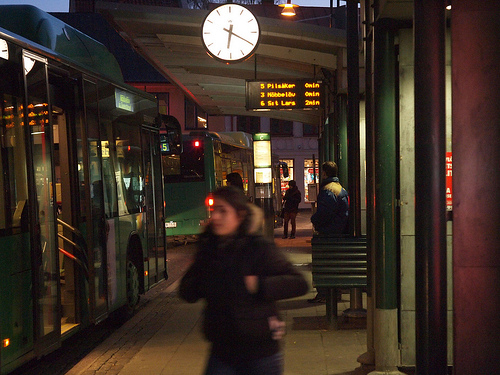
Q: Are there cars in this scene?
A: No, there are no cars.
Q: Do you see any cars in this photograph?
A: No, there are no cars.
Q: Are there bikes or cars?
A: No, there are no cars or bikes.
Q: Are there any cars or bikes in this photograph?
A: No, there are no cars or bikes.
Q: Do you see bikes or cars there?
A: No, there are no cars or bikes.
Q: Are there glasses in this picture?
A: No, there are no glasses.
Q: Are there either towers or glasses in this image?
A: No, there are no glasses or towers.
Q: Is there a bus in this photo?
A: Yes, there is a bus.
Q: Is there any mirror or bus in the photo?
A: Yes, there is a bus.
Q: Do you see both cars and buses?
A: No, there is a bus but no cars.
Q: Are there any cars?
A: No, there are no cars.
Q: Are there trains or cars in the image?
A: No, there are no cars or trains.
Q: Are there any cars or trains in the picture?
A: No, there are no cars or trains.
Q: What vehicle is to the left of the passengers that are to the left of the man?
A: The vehicle is a bus.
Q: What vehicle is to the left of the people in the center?
A: The vehicle is a bus.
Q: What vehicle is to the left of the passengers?
A: The vehicle is a bus.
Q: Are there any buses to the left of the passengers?
A: Yes, there is a bus to the left of the passengers.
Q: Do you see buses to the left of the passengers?
A: Yes, there is a bus to the left of the passengers.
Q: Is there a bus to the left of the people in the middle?
A: Yes, there is a bus to the left of the passengers.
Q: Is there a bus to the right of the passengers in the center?
A: No, the bus is to the left of the passengers.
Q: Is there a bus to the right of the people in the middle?
A: No, the bus is to the left of the passengers.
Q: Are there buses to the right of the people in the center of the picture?
A: No, the bus is to the left of the passengers.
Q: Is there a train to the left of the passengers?
A: No, there is a bus to the left of the passengers.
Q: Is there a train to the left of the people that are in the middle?
A: No, there is a bus to the left of the passengers.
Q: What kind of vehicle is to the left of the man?
A: The vehicle is a bus.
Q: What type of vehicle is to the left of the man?
A: The vehicle is a bus.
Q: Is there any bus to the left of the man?
A: Yes, there is a bus to the left of the man.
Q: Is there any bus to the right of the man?
A: No, the bus is to the left of the man.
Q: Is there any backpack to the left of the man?
A: No, there is a bus to the left of the man.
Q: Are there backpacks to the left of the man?
A: No, there is a bus to the left of the man.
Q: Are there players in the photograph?
A: No, there are no players.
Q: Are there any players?
A: No, there are no players.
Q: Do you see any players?
A: No, there are no players.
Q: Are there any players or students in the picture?
A: No, there are no players or students.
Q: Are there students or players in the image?
A: No, there are no players or students.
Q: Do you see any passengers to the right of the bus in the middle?
A: Yes, there are passengers to the right of the bus.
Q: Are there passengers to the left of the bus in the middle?
A: No, the passengers are to the right of the bus.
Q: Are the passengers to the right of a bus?
A: Yes, the passengers are to the right of a bus.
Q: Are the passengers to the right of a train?
A: No, the passengers are to the right of a bus.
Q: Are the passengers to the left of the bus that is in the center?
A: No, the passengers are to the right of the bus.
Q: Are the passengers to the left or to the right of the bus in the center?
A: The passengers are to the right of the bus.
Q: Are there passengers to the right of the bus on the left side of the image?
A: Yes, there are passengers to the right of the bus.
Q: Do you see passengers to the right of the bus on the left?
A: Yes, there are passengers to the right of the bus.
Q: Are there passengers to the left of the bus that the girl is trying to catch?
A: No, the passengers are to the right of the bus.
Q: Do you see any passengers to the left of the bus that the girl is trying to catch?
A: No, the passengers are to the right of the bus.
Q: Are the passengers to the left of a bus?
A: No, the passengers are to the right of a bus.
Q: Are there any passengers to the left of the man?
A: Yes, there are passengers to the left of the man.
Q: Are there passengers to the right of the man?
A: No, the passengers are to the left of the man.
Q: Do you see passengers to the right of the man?
A: No, the passengers are to the left of the man.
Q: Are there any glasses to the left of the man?
A: No, there are passengers to the left of the man.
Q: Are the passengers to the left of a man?
A: Yes, the passengers are to the left of a man.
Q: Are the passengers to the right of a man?
A: No, the passengers are to the left of a man.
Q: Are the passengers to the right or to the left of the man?
A: The passengers are to the left of the man.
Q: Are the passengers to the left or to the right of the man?
A: The passengers are to the left of the man.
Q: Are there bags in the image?
A: No, there are no bags.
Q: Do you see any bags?
A: No, there are no bags.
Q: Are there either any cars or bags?
A: No, there are no bags or cars.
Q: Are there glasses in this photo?
A: No, there are no glasses.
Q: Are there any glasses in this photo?
A: No, there are no glasses.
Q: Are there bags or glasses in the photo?
A: No, there are no glasses or bags.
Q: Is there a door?
A: Yes, there is a door.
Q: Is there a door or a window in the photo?
A: Yes, there is a door.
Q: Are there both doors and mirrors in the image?
A: Yes, there are both a door and a mirror.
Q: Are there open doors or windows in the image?
A: Yes, there is an open door.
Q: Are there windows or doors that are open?
A: Yes, the door is open.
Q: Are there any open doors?
A: Yes, there is an open door.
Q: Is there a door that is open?
A: Yes, there is a door that is open.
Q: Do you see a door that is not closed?
A: Yes, there is a open door.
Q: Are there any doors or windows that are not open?
A: No, there is a door but it is open.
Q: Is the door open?
A: Yes, the door is open.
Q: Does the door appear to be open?
A: Yes, the door is open.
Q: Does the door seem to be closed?
A: No, the door is open.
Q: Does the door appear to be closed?
A: No, the door is open.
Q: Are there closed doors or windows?
A: No, there is a door but it is open.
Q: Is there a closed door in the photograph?
A: No, there is a door but it is open.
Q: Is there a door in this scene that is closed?
A: No, there is a door but it is open.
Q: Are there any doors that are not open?
A: No, there is a door but it is open.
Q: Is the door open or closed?
A: The door is open.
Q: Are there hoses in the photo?
A: No, there are no hoses.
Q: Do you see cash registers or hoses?
A: No, there are no hoses or cash registers.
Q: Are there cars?
A: No, there are no cars.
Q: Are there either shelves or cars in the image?
A: No, there are no cars or shelves.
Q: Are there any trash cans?
A: No, there are no trash cans.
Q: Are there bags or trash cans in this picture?
A: No, there are no trash cans or bags.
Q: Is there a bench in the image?
A: Yes, there is a bench.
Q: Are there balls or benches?
A: Yes, there is a bench.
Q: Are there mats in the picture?
A: No, there are no mats.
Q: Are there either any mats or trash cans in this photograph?
A: No, there are no mats or trash cans.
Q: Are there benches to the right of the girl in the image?
A: Yes, there is a bench to the right of the girl.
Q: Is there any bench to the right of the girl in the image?
A: Yes, there is a bench to the right of the girl.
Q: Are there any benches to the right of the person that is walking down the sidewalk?
A: Yes, there is a bench to the right of the girl.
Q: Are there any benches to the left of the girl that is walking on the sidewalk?
A: No, the bench is to the right of the girl.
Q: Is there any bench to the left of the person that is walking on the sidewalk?
A: No, the bench is to the right of the girl.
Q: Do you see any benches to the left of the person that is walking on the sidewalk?
A: No, the bench is to the right of the girl.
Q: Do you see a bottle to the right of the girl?
A: No, there is a bench to the right of the girl.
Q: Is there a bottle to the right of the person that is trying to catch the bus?
A: No, there is a bench to the right of the girl.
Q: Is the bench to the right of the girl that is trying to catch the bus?
A: Yes, the bench is to the right of the girl.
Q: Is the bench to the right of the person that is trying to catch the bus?
A: Yes, the bench is to the right of the girl.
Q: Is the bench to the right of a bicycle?
A: No, the bench is to the right of the girl.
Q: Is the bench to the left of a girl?
A: No, the bench is to the right of a girl.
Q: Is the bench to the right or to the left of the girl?
A: The bench is to the right of the girl.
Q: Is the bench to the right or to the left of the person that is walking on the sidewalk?
A: The bench is to the right of the girl.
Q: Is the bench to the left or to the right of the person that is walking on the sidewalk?
A: The bench is to the right of the girl.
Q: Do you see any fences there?
A: No, there are no fences.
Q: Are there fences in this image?
A: No, there are no fences.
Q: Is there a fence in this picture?
A: No, there are no fences.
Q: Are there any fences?
A: No, there are no fences.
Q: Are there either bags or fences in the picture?
A: No, there are no fences or bags.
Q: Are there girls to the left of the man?
A: Yes, there is a girl to the left of the man.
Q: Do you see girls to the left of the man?
A: Yes, there is a girl to the left of the man.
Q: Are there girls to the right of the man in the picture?
A: No, the girl is to the left of the man.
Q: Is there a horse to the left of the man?
A: No, there is a girl to the left of the man.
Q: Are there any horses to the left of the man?
A: No, there is a girl to the left of the man.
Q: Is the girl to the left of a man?
A: Yes, the girl is to the left of a man.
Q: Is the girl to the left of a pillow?
A: No, the girl is to the left of a man.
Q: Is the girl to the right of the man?
A: No, the girl is to the left of the man.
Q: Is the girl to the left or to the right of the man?
A: The girl is to the left of the man.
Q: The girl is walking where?
A: The girl is walking on the side walk.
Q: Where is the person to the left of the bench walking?
A: The girl is walking on the side walk.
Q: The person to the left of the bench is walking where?
A: The girl is walking on the side walk.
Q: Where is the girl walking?
A: The girl is walking on the side walk.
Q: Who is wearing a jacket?
A: The girl is wearing a jacket.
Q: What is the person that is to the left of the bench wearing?
A: The girl is wearing a jacket.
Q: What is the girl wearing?
A: The girl is wearing a jacket.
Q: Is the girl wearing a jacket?
A: Yes, the girl is wearing a jacket.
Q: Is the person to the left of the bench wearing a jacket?
A: Yes, the girl is wearing a jacket.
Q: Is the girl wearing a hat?
A: No, the girl is wearing a jacket.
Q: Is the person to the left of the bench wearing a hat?
A: No, the girl is wearing a jacket.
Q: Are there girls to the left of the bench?
A: Yes, there is a girl to the left of the bench.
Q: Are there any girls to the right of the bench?
A: No, the girl is to the left of the bench.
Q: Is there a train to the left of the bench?
A: No, there is a girl to the left of the bench.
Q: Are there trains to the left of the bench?
A: No, there is a girl to the left of the bench.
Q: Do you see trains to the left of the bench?
A: No, there is a girl to the left of the bench.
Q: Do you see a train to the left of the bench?
A: No, there is a girl to the left of the bench.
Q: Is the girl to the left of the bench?
A: Yes, the girl is to the left of the bench.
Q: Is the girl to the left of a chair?
A: No, the girl is to the left of the bench.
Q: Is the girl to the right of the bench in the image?
A: No, the girl is to the left of the bench.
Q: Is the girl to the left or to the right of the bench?
A: The girl is to the left of the bench.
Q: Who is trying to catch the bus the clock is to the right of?
A: The girl is trying to catch the bus.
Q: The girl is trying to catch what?
A: The girl is trying to catch the bus.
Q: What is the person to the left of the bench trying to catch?
A: The girl is trying to catch the bus.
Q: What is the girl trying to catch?
A: The girl is trying to catch the bus.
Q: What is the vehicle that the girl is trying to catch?
A: The vehicle is a bus.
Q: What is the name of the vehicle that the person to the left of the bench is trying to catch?
A: The vehicle is a bus.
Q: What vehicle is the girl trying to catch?
A: The girl is trying to catch the bus.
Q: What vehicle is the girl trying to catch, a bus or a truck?
A: The girl is trying to catch a bus.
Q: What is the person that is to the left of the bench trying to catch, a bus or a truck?
A: The girl is trying to catch a bus.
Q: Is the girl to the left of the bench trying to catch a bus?
A: Yes, the girl is trying to catch a bus.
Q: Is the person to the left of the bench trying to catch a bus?
A: Yes, the girl is trying to catch a bus.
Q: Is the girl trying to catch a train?
A: No, the girl is trying to catch a bus.